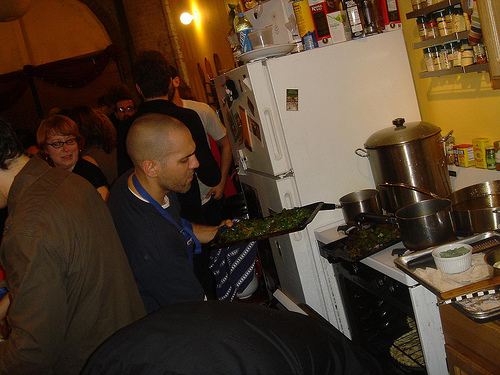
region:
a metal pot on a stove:
[310, 188, 390, 229]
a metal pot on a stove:
[355, 199, 462, 251]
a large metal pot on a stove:
[375, 179, 499, 239]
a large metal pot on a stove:
[352, 117, 457, 214]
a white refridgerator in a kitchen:
[213, 33, 448, 364]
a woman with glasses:
[38, 130, 81, 149]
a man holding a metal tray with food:
[204, 199, 324, 246]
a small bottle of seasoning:
[420, 45, 440, 74]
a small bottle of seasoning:
[414, 14, 431, 44]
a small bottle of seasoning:
[442, 6, 460, 35]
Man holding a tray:
[213, 200, 323, 245]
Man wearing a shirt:
[107, 164, 212, 306]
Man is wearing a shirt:
[101, 165, 208, 313]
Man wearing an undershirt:
[129, 170, 171, 212]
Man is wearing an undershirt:
[122, 166, 172, 214]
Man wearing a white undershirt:
[125, 168, 172, 210]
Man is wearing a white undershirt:
[122, 157, 176, 212]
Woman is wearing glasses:
[46, 134, 83, 149]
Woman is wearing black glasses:
[43, 130, 84, 150]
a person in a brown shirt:
[0, 124, 145, 372]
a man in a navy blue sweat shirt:
[106, 112, 236, 314]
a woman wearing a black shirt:
[33, 115, 109, 199]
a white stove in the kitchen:
[273, 165, 498, 374]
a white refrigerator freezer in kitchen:
[210, 27, 423, 339]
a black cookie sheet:
[209, 202, 320, 249]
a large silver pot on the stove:
[358, 120, 452, 214]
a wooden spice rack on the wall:
[404, 0, 489, 81]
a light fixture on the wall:
[178, 10, 200, 24]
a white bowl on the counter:
[433, 242, 471, 272]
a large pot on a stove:
[356, 117, 456, 208]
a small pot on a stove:
[334, 184, 383, 224]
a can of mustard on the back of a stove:
[471, 135, 490, 168]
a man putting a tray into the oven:
[114, 111, 233, 301]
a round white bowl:
[432, 238, 475, 275]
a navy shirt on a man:
[105, 168, 216, 312]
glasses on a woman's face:
[45, 135, 79, 149]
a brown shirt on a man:
[0, 152, 145, 371]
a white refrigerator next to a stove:
[214, 25, 425, 337]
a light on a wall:
[177, 6, 199, 31]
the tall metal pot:
[355, 116, 454, 213]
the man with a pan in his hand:
[105, 112, 323, 302]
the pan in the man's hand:
[212, 200, 322, 245]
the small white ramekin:
[430, 242, 472, 274]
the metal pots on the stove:
[318, 118, 498, 250]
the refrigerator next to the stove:
[212, 30, 420, 341]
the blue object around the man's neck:
[130, 163, 205, 255]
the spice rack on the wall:
[405, 0, 487, 76]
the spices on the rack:
[412, 0, 487, 71]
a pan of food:
[200, 188, 324, 253]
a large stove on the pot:
[360, 102, 457, 230]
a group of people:
[8, 28, 248, 348]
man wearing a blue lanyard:
[130, 174, 214, 259]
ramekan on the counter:
[425, 240, 482, 276]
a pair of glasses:
[39, 132, 83, 162]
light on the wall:
[168, 2, 200, 30]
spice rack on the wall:
[396, 0, 498, 105]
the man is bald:
[98, 100, 210, 310]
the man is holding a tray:
[124, 115, 262, 292]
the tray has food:
[199, 193, 319, 258]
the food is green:
[214, 157, 320, 263]